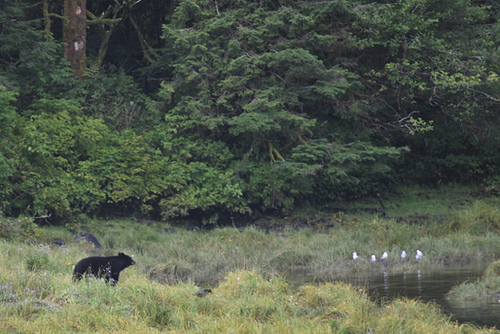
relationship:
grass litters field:
[68, 181, 489, 287] [27, 124, 481, 327]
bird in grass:
[191, 287, 212, 298] [17, 163, 478, 309]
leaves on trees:
[170, 89, 254, 139] [35, 15, 144, 138]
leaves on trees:
[161, 52, 351, 188] [3, 5, 498, 231]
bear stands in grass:
[71, 251, 135, 287] [1, 197, 496, 329]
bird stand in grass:
[347, 250, 364, 265] [2, 220, 498, 332]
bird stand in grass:
[361, 250, 380, 271] [2, 220, 498, 332]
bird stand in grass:
[375, 247, 390, 267] [2, 220, 498, 332]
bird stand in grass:
[392, 241, 409, 265] [2, 220, 498, 332]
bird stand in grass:
[408, 242, 427, 264] [2, 220, 498, 332]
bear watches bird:
[71, 251, 135, 287] [349, 250, 361, 260]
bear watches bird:
[71, 251, 135, 287] [369, 253, 377, 261]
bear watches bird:
[71, 251, 135, 287] [380, 251, 389, 261]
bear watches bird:
[71, 251, 135, 287] [399, 250, 407, 260]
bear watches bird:
[71, 251, 135, 287] [413, 248, 424, 259]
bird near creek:
[415, 249, 424, 261] [281, 263, 500, 330]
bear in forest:
[71, 251, 135, 287] [3, 2, 495, 332]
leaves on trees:
[406, 111, 435, 138] [217, 14, 344, 179]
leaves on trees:
[15, 117, 162, 205] [60, 0, 90, 78]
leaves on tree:
[406, 115, 435, 136] [32, 14, 289, 236]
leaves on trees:
[407, 112, 435, 137] [3, 5, 498, 231]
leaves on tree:
[1, 2, 499, 214] [61, 0, 88, 74]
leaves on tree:
[1, 2, 499, 214] [38, 0, 55, 40]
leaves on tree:
[1, 2, 499, 214] [325, 27, 467, 165]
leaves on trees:
[1, 2, 499, 214] [3, 5, 498, 231]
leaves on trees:
[363, 58, 427, 108] [3, 5, 498, 231]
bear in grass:
[71, 251, 135, 287] [0, 184, 499, 330]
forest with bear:
[3, 5, 498, 222] [71, 245, 140, 297]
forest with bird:
[3, 5, 498, 222] [348, 248, 363, 265]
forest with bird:
[3, 5, 498, 222] [368, 248, 377, 267]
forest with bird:
[3, 5, 498, 222] [379, 244, 392, 264]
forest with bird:
[3, 5, 498, 222] [397, 246, 410, 262]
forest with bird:
[3, 5, 498, 222] [414, 244, 425, 261]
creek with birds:
[294, 260, 498, 330] [412, 248, 426, 260]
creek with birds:
[294, 260, 498, 330] [398, 247, 405, 261]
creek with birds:
[294, 260, 498, 330] [379, 250, 387, 259]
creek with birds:
[294, 260, 498, 330] [367, 251, 375, 264]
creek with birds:
[294, 260, 498, 330] [349, 250, 359, 262]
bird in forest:
[192, 286, 212, 299] [1, 1, 499, 252]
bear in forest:
[70, 249, 135, 298] [1, 1, 499, 252]